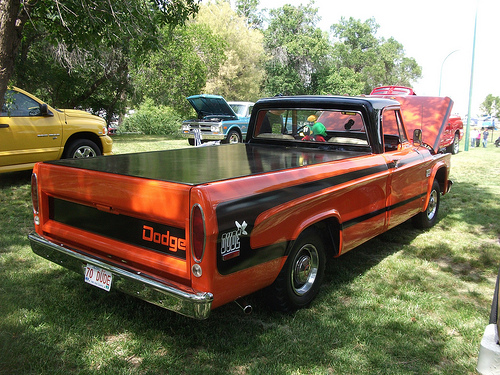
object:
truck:
[27, 94, 454, 320]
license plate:
[84, 262, 113, 292]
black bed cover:
[41, 143, 373, 187]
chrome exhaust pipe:
[234, 298, 254, 316]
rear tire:
[271, 228, 329, 311]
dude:
[219, 219, 250, 255]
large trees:
[0, 0, 422, 137]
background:
[0, 0, 500, 170]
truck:
[180, 94, 302, 146]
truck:
[0, 83, 114, 174]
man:
[301, 114, 328, 139]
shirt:
[310, 122, 328, 138]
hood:
[310, 95, 454, 152]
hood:
[186, 94, 240, 120]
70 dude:
[86, 267, 112, 286]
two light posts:
[437, 10, 477, 152]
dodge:
[141, 223, 188, 253]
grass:
[0, 122, 499, 374]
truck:
[368, 85, 464, 154]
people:
[480, 129, 490, 149]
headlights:
[209, 125, 220, 134]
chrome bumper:
[28, 232, 215, 321]